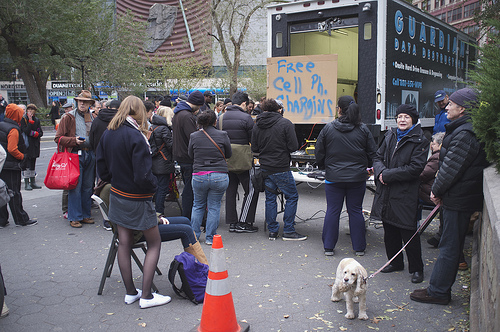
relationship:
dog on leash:
[330, 257, 368, 320] [361, 202, 441, 283]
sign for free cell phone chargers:
[267, 55, 335, 123] [283, 53, 343, 136]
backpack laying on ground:
[168, 250, 209, 305] [3, 119, 483, 324]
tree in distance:
[8, 8, 151, 107] [67, 50, 156, 114]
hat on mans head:
[70, 77, 103, 103] [446, 84, 467, 149]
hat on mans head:
[448, 81, 481, 108] [441, 86, 482, 121]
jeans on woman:
[184, 162, 227, 215] [96, 94, 172, 309]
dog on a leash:
[330, 257, 368, 320] [375, 200, 437, 310]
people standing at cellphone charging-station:
[113, 92, 300, 309] [281, 141, 401, 186]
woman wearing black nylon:
[102, 90, 161, 202] [136, 217, 164, 294]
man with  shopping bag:
[54, 85, 101, 232] [39, 143, 84, 193]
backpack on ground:
[169, 250, 209, 303] [0, 175, 471, 330]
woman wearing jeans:
[200, 115, 223, 214] [186, 165, 227, 231]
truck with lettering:
[265, 2, 495, 182] [394, 10, 467, 89]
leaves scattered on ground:
[283, 313, 288, 317] [0, 175, 471, 330]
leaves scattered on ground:
[306, 310, 334, 327] [0, 175, 471, 330]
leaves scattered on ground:
[314, 272, 323, 281] [0, 175, 471, 330]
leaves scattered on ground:
[372, 284, 384, 296] [0, 175, 471, 330]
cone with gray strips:
[187, 231, 254, 328] [200, 230, 230, 302]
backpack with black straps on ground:
[168, 250, 209, 305] [26, 163, 458, 330]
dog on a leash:
[322, 192, 442, 323] [379, 215, 419, 295]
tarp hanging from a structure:
[142, 2, 178, 52] [115, 0, 211, 74]